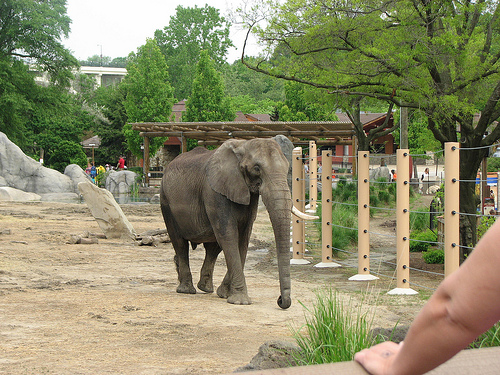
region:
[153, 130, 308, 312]
elephant holding a ball in its trunk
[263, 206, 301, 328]
elephant trunk holding a ball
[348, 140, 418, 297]
wires and fencing around an elephant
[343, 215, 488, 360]
white arm leaning on a fence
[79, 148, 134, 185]
crowd of people at a zoo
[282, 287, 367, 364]
green grass growing in an elephant pen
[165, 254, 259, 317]
wrinkly legs of an elephant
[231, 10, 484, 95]
green leaves on a tree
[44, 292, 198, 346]
sandy floor of an elephant pen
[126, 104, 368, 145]
pavilion roof in an elephant enclosure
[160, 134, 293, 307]
a large grey elephant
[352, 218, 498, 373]
a person's left arm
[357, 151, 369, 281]
a thick wooden post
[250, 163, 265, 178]
an elephant's right eye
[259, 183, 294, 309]
an elephant's long trunk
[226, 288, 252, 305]
an elephant's right front foot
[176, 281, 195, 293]
an elephant's right rear foot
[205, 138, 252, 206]
an elephant's right ear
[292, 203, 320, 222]
an elephant's left tusk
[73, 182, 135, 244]
a big rock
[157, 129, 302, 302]
small grey elephant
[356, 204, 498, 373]
part of an arm of a white people in the right side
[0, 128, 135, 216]
grey rocks in the back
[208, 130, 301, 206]
big ears of a small elephant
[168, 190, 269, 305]
four grey legs of a small elephant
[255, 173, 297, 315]
large grey trunk of a small elephant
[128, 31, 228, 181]
two green pines in the back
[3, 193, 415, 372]
brown ground without grass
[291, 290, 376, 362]
green grass in the elephant cage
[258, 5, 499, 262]
big tree with green leaves and brown stem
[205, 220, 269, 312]
gray elephant with crossed legs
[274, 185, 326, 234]
single white tusk on elephant's face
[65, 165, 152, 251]
lone white boulder on the ground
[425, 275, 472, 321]
small dimple in person's arm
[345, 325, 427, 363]
hand resting on the railing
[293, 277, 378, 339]
large blades of tall green grass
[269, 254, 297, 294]
marks in the gray trunk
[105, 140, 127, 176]
man wearing orange shirt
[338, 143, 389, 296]
large rounded pink poles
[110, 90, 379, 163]
large brown wooden roof on building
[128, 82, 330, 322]
elephant in photograph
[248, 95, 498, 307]
fence separating elephant from people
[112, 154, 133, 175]
person in red shirt in background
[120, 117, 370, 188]
brown building in photograph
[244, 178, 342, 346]
elephants trunk touching the ground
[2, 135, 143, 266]
grey rocks in background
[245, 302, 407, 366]
small patch of grass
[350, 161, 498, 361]
persons arm on wooden fence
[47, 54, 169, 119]
white building in background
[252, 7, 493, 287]
large tree in photograph